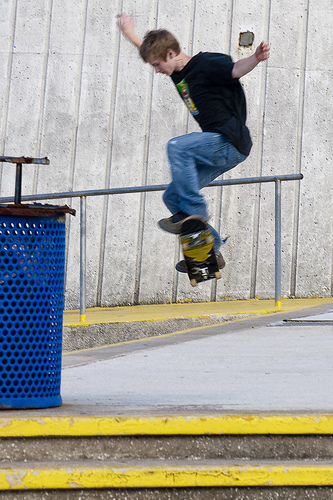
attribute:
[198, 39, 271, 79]
arm — stretched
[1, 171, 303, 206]
railing — metal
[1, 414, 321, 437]
step — yellow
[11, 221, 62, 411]
bin — blue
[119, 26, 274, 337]
boy — skateboarding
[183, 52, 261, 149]
shirt — blue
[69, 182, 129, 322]
railing — metal, gray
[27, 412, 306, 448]
line — yellow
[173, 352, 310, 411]
ground — paved